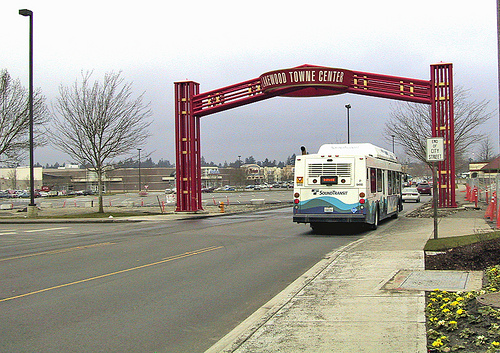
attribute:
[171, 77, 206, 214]
metal — red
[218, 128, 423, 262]
bus — white and blue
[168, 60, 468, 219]
gate — giant, red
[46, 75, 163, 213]
tree — brown, bare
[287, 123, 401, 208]
car — family, RV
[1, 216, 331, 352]
road — dark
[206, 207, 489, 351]
sidewalk — dirty, cement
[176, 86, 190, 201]
decaorations — yellow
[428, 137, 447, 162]
street sign — white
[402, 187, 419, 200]
car — white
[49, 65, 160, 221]
tree — leafless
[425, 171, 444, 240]
pole — silver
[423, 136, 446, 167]
sign — white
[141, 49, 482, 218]
archway — red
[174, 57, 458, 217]
archway — big, red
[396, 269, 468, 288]
electrical entryway — Sewer 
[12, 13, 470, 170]
sky — dark, grey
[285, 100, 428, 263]
bus — white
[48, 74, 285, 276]
building — brown, large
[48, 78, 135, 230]
tree — leafless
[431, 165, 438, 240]
pole — street sign 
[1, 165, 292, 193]
shopping center — long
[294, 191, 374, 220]
artwork — blue